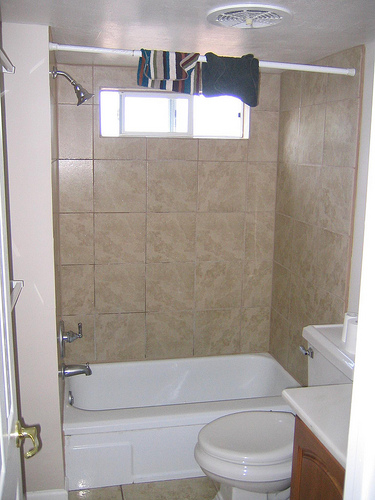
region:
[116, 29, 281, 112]
towels laying on shower curtain rod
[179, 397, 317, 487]
toilet seat and lid are down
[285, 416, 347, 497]
cabinet is made of wood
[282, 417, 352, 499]
the cabinet is brown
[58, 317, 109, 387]
bath tub faucet is silver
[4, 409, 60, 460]
door handle is gold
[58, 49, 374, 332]
shower wall is brown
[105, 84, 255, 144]
bathroom window is open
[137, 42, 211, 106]
the towel is striped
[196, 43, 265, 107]
the towel is black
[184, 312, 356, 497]
a white porcelain toilet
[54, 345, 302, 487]
a white porcelain bath tub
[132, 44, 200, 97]
a multicolored towel hanging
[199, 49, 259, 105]
a dark colored towel hanging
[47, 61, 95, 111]
a bathroom shower head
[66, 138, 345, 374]
tan tiled shower wall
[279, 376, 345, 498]
bathroom vanity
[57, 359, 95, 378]
bathtub faucet spout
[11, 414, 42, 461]
a gold colored door handle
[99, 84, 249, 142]
a white framed open window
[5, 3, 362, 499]
a bathroom has bathtub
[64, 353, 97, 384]
faucett of bathtub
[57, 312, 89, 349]
handle of faucett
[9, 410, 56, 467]
handle of a door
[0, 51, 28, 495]
white door of a bathroom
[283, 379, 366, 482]
top of a counter is white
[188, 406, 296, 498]
toilet is close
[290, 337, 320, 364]
handle of toilet tank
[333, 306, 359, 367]
two toilet papers on a toilet tank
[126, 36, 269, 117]
two small towels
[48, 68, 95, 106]
silver shower head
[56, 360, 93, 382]
silver bathtub spout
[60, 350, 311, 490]
white bathtub with a silver spout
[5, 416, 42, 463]
gold handle on a white bathroom door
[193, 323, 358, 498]
white toilet with a silver handle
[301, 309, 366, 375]
two rolls of toilet paper on top of the toilet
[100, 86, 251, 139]
bathroom window on shower wall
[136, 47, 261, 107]
two wash cloths hanging from a white rod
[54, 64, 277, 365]
tan shower wall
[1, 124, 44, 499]
white bathroom door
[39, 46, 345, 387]
the shower wall is tiled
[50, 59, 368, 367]
the shower wall is brown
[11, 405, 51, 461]
the door handle is gold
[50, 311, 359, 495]
the toilet is beside the bathtub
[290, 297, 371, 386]
rolls of toilet paper on the toilet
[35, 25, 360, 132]
washcloths are hanging from the shower rod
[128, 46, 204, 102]
the washcloth is striped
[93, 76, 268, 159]
a small window in the shower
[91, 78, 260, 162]
the window is open